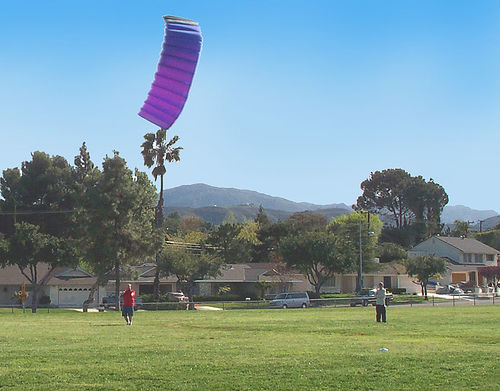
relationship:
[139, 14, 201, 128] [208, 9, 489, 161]
kite in sky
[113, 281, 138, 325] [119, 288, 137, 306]
man wearing shirt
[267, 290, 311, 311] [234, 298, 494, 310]
van on street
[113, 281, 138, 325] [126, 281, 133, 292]
man has head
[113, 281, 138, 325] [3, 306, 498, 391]
man on grass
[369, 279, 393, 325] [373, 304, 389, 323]
man wearing pants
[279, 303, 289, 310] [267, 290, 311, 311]
front tire on van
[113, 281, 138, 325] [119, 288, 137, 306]
man in shirt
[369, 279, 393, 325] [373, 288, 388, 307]
man in shirt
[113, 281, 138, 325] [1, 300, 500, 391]
man in field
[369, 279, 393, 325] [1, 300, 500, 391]
man in field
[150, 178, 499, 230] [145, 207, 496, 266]
mountain behind trees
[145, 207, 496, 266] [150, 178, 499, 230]
trees in front of mountain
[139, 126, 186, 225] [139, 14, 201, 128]
palm tree under kite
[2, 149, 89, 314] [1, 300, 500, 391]
tree in field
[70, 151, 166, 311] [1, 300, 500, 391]
tree in field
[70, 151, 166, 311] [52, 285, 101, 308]
tree in front of garage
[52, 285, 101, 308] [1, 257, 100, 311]
garage on home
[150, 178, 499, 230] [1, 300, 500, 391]
mountain view from field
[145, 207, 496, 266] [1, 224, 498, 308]
trees by houses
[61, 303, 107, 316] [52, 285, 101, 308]
driveway to garage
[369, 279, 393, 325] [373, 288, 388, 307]
man wearing shirt